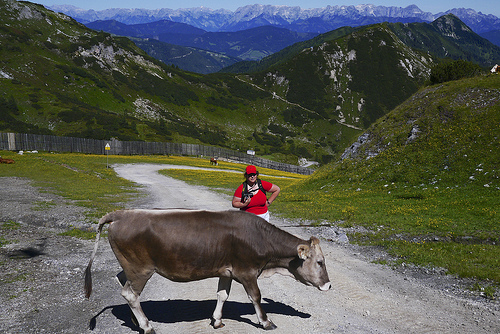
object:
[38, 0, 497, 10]
sky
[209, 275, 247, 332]
leg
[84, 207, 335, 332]
cow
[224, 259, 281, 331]
cow leg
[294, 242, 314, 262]
ear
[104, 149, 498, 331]
path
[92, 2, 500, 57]
mountains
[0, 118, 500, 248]
grass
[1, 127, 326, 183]
fence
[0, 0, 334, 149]
mountains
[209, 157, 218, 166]
animal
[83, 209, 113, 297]
tail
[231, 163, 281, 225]
woman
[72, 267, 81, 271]
rocks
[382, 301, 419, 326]
pebbles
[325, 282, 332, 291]
nose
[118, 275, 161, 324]
leg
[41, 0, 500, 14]
clouds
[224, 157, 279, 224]
person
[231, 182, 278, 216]
red shirt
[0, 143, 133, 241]
area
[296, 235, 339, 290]
face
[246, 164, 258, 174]
cap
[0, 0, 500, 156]
background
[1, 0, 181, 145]
side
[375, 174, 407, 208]
flowers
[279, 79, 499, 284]
hill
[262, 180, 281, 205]
arm